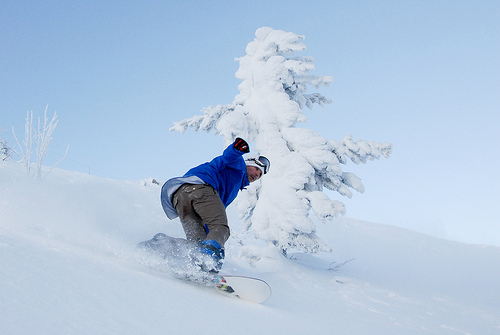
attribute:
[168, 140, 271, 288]
person — snowboarding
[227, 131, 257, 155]
glove — red, black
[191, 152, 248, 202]
jacket — blue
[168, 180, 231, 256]
pants — gray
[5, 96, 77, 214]
tree — snow covered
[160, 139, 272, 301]
snowboarder — hurdling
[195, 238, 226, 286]
boot — blue, semi-covered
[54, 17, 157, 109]
sky — beautiful, ice blue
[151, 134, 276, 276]
man — blue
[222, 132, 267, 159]
glove — black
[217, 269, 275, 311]
board — white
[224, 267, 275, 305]
snowboard — white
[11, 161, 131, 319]
slope — pristine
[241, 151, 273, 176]
glasses — white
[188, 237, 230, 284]
boot — blue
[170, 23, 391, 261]
tree — behind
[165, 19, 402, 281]
tree — crusted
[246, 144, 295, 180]
hat — white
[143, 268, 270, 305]
snowboard — kicking up